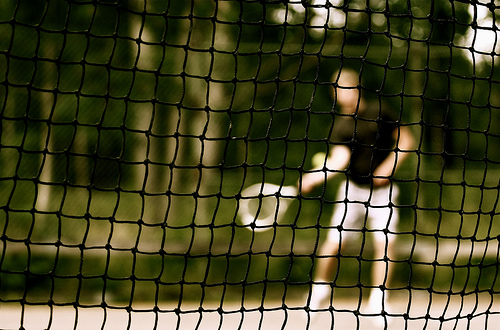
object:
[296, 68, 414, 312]
player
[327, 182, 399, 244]
shorts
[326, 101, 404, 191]
shirt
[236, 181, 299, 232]
tennis racket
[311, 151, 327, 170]
tennis ball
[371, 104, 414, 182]
left arm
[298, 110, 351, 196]
right arm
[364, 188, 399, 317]
left leg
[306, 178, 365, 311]
right leg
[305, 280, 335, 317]
shoes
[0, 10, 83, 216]
trees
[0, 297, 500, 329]
tennis court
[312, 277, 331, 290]
socks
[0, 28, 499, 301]
fence